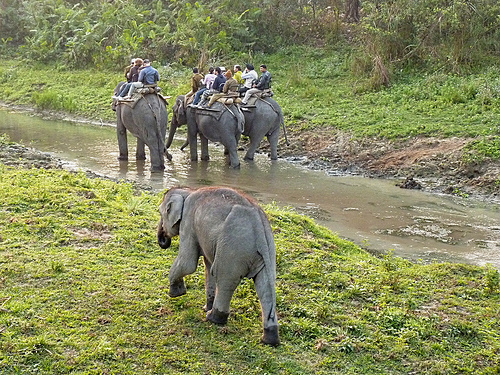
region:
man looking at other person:
[245, 61, 280, 95]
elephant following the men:
[142, 185, 277, 339]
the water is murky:
[273, 170, 498, 218]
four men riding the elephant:
[187, 61, 230, 98]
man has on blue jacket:
[135, 55, 162, 84]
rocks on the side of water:
[317, 137, 497, 207]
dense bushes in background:
[271, 4, 498, 87]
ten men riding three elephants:
[112, 59, 269, 99]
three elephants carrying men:
[105, 95, 286, 170]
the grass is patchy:
[2, 191, 161, 359]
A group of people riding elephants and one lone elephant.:
[35, 37, 360, 373]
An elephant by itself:
[84, 176, 329, 351]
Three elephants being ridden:
[79, 43, 326, 185]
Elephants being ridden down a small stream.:
[8, 16, 468, 258]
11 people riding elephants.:
[97, 37, 299, 114]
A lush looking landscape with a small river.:
[26, 11, 492, 366]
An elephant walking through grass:
[98, 181, 389, 357]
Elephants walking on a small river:
[47, 29, 353, 179]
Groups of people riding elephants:
[104, 42, 336, 112]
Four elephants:
[68, 25, 320, 364]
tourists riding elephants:
[104, 47, 334, 179]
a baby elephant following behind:
[155, 168, 308, 373]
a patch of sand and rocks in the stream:
[389, 207, 458, 244]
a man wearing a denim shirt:
[141, 62, 158, 87]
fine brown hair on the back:
[203, 182, 239, 199]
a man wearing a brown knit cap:
[223, 66, 240, 102]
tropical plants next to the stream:
[72, 7, 245, 59]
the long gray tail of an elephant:
[147, 109, 178, 159]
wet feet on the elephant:
[206, 302, 293, 347]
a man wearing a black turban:
[245, 62, 257, 89]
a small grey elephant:
[150, 175, 294, 348]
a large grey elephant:
[102, 77, 169, 171]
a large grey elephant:
[163, 89, 245, 175]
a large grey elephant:
[218, 82, 285, 164]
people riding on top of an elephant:
[107, 52, 173, 169]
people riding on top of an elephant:
[171, 60, 246, 172]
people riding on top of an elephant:
[229, 60, 285, 160]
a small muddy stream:
[2, 93, 497, 268]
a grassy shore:
[2, 149, 490, 370]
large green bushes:
[19, 4, 244, 63]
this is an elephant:
[148, 181, 260, 346]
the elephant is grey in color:
[145, 191, 270, 342]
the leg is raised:
[161, 257, 194, 302]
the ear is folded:
[165, 191, 180, 221]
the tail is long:
[256, 255, 277, 306]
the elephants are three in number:
[115, 92, 271, 167]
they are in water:
[115, 100, 270, 165]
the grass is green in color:
[28, 245, 115, 348]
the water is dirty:
[356, 195, 412, 240]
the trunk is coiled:
[152, 230, 168, 248]